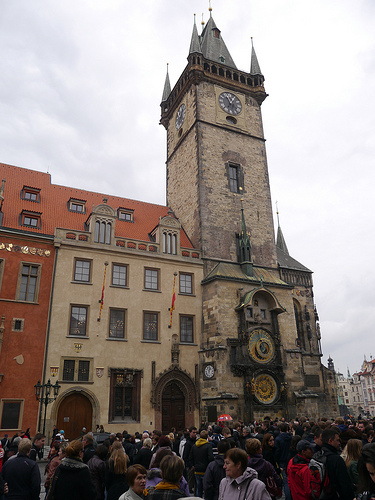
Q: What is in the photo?
A: Clock.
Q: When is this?
A: Daytime.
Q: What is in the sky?
A: Clouds.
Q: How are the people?
A: Gathered.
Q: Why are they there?
A: Pulic gathering.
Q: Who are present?
A: People.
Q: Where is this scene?
A: Near building.